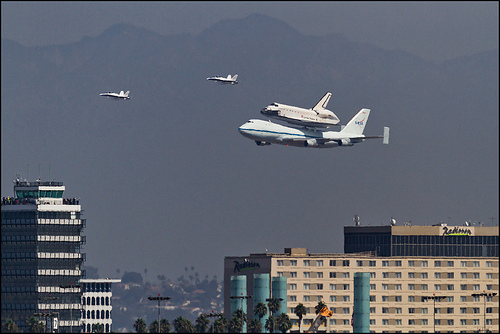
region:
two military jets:
[83, 60, 245, 111]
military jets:
[85, 62, 245, 109]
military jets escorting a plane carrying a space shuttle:
[88, 62, 403, 162]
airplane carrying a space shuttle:
[234, 95, 396, 151]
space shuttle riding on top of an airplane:
[256, 84, 346, 135]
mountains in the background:
[4, 11, 494, 64]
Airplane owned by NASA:
[227, 103, 401, 158]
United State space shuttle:
[254, 85, 346, 131]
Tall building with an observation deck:
[0, 174, 92, 332]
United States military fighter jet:
[89, 79, 139, 107]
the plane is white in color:
[239, 108, 372, 150]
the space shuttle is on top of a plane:
[236, 90, 371, 158]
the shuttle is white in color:
[263, 90, 340, 130]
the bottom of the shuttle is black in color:
[265, 111, 342, 128]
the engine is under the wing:
[335, 135, 351, 142]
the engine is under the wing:
[307, 135, 327, 146]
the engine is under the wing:
[258, 137, 269, 146]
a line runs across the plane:
[240, 125, 317, 137]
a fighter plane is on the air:
[209, 71, 239, 83]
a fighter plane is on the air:
[103, 88, 135, 104]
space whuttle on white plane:
[229, 96, 387, 160]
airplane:
[99, 80, 130, 103]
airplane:
[202, 59, 243, 94]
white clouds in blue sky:
[9, 25, 51, 61]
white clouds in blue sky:
[123, 191, 160, 211]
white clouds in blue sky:
[238, 172, 302, 224]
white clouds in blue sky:
[361, 32, 432, 72]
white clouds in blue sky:
[421, 18, 459, 75]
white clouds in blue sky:
[433, 137, 474, 168]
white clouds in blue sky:
[147, 159, 199, 192]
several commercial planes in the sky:
[76, 54, 416, 186]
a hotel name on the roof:
[440, 217, 480, 238]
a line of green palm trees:
[133, 295, 341, 331]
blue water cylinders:
[229, 272, 297, 315]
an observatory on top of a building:
[14, 171, 62, 200]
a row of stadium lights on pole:
[143, 294, 171, 306]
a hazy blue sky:
[27, 7, 481, 70]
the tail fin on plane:
[346, 101, 376, 134]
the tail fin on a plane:
[232, 71, 244, 81]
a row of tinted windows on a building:
[396, 231, 496, 258]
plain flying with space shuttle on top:
[230, 80, 422, 199]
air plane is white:
[228, 104, 385, 156]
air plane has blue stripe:
[224, 100, 394, 160]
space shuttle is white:
[252, 88, 347, 129]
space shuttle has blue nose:
[251, 97, 281, 122]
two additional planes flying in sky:
[83, 60, 252, 118]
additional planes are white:
[55, 49, 264, 115]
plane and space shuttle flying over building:
[215, 90, 497, 332]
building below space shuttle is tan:
[167, 162, 497, 332]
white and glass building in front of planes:
[0, 158, 145, 331]